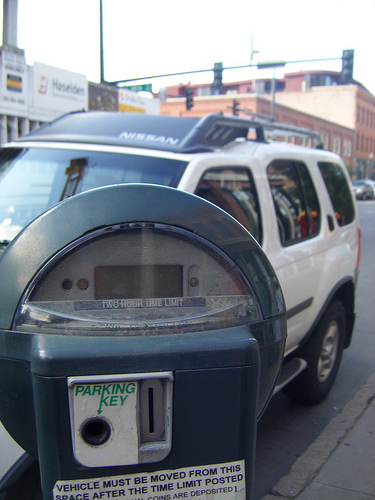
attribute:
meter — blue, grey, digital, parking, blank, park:
[29, 197, 282, 486]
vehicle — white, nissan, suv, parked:
[246, 108, 351, 309]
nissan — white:
[119, 124, 180, 154]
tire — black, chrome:
[286, 296, 344, 408]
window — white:
[265, 149, 325, 263]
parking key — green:
[63, 383, 118, 412]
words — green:
[71, 364, 99, 419]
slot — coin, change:
[140, 384, 169, 435]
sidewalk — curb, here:
[323, 450, 365, 467]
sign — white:
[114, 303, 180, 356]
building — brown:
[199, 86, 341, 130]